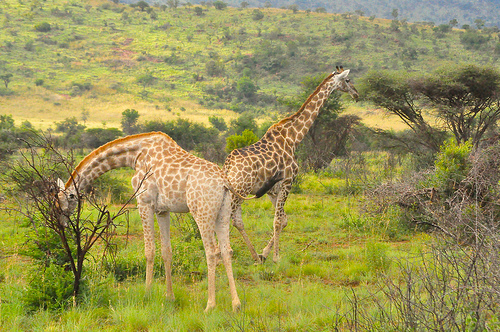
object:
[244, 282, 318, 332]
grass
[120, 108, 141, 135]
tree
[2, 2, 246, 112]
hill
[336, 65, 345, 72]
horns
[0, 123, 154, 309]
bush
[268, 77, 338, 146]
neck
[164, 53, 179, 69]
tree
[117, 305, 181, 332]
grass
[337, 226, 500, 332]
tree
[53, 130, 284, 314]
giraffe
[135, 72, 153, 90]
tree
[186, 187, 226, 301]
leg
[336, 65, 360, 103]
giraffe head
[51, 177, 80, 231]
giraffe head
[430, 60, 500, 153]
tree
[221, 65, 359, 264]
giraffe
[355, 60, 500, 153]
large bush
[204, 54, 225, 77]
tree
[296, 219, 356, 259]
grass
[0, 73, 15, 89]
tree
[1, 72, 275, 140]
hillside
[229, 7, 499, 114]
hillside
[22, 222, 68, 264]
leaves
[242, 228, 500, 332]
ground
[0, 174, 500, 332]
area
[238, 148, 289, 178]
spots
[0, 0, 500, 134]
background